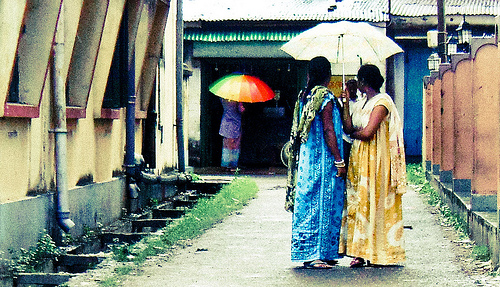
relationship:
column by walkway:
[461, 32, 496, 209] [251, 169, 461, 283]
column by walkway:
[414, 40, 495, 236] [203, 147, 302, 273]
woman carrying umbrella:
[211, 92, 283, 199] [198, 57, 305, 139]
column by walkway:
[21, 0, 62, 105] [75, 151, 480, 280]